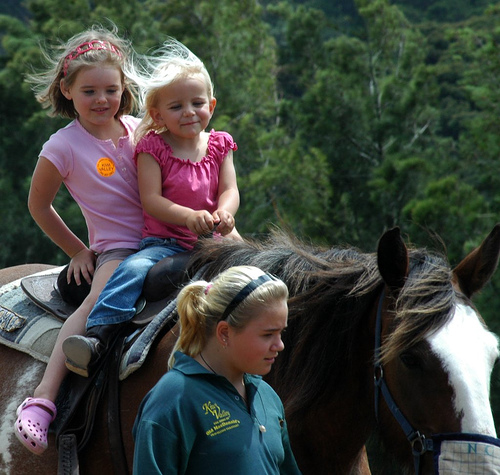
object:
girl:
[60, 35, 241, 378]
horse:
[0, 223, 500, 475]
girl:
[13, 16, 151, 455]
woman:
[131, 264, 302, 474]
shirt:
[131, 347, 302, 474]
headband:
[216, 270, 279, 325]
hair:
[164, 264, 290, 367]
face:
[394, 302, 499, 474]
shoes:
[61, 333, 103, 377]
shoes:
[12, 396, 57, 455]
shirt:
[131, 127, 238, 252]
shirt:
[36, 114, 149, 255]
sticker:
[95, 156, 116, 176]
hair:
[127, 34, 214, 141]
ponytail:
[166, 280, 210, 370]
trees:
[263, 2, 499, 215]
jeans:
[84, 235, 189, 329]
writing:
[201, 400, 241, 437]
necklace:
[198, 351, 268, 433]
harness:
[373, 288, 499, 474]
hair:
[23, 17, 144, 120]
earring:
[220, 337, 227, 344]